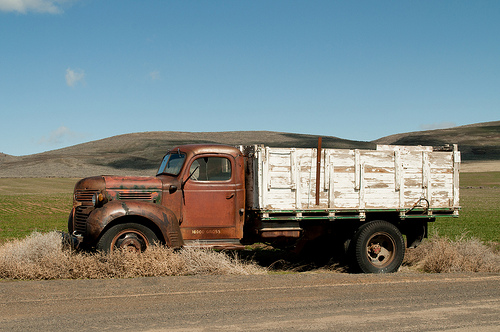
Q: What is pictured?
A: A truck.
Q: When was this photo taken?
A: Daytime.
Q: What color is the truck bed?
A: White.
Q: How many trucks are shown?
A: 1.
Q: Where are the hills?
A: Behind the truck.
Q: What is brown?
A: The truck.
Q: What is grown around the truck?
A: Dead grass.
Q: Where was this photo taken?
A: Along the side of a country road.